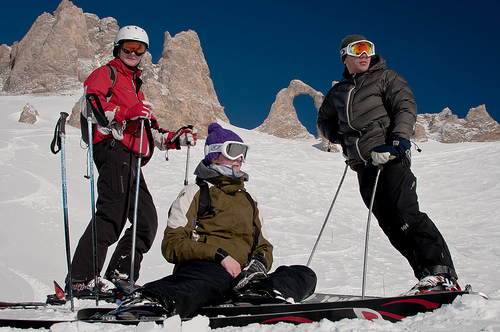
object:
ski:
[74, 286, 466, 330]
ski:
[1, 292, 151, 309]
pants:
[348, 167, 461, 282]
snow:
[0, 113, 499, 332]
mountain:
[143, 28, 227, 135]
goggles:
[203, 140, 250, 163]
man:
[109, 121, 319, 321]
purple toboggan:
[205, 122, 248, 161]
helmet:
[111, 24, 151, 55]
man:
[63, 24, 199, 295]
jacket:
[74, 57, 200, 160]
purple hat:
[203, 121, 249, 167]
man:
[313, 31, 456, 292]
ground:
[273, 150, 314, 228]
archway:
[248, 77, 338, 153]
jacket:
[161, 159, 275, 271]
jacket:
[314, 53, 418, 173]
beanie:
[202, 120, 243, 164]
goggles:
[340, 40, 376, 58]